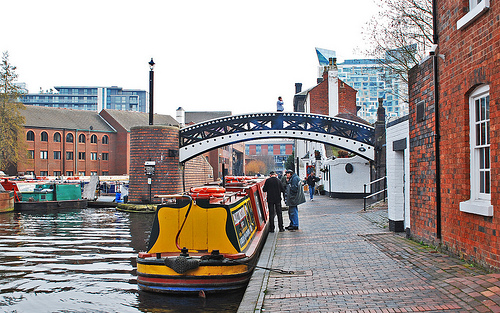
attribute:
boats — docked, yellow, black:
[137, 174, 269, 293]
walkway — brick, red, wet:
[238, 186, 500, 312]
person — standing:
[277, 96, 284, 115]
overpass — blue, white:
[179, 112, 374, 161]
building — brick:
[410, 1, 500, 270]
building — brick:
[17, 104, 133, 176]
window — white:
[459, 80, 494, 216]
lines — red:
[271, 238, 375, 249]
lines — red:
[265, 284, 442, 300]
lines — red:
[338, 302, 464, 311]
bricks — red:
[419, 161, 428, 170]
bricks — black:
[408, 138, 422, 147]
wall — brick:
[409, 55, 441, 246]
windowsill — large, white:
[459, 197, 493, 218]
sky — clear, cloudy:
[2, 2, 434, 114]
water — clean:
[0, 208, 247, 312]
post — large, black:
[149, 71, 155, 126]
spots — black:
[284, 130, 305, 135]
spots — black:
[185, 145, 197, 151]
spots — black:
[221, 133, 240, 141]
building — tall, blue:
[314, 45, 418, 117]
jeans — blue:
[289, 205, 300, 228]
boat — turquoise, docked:
[18, 182, 87, 212]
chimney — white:
[328, 57, 339, 118]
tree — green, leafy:
[2, 48, 30, 170]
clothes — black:
[262, 177, 285, 229]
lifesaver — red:
[189, 185, 226, 201]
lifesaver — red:
[226, 174, 250, 185]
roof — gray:
[20, 105, 181, 133]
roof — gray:
[186, 111, 229, 124]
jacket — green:
[287, 173, 306, 206]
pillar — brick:
[130, 126, 184, 203]